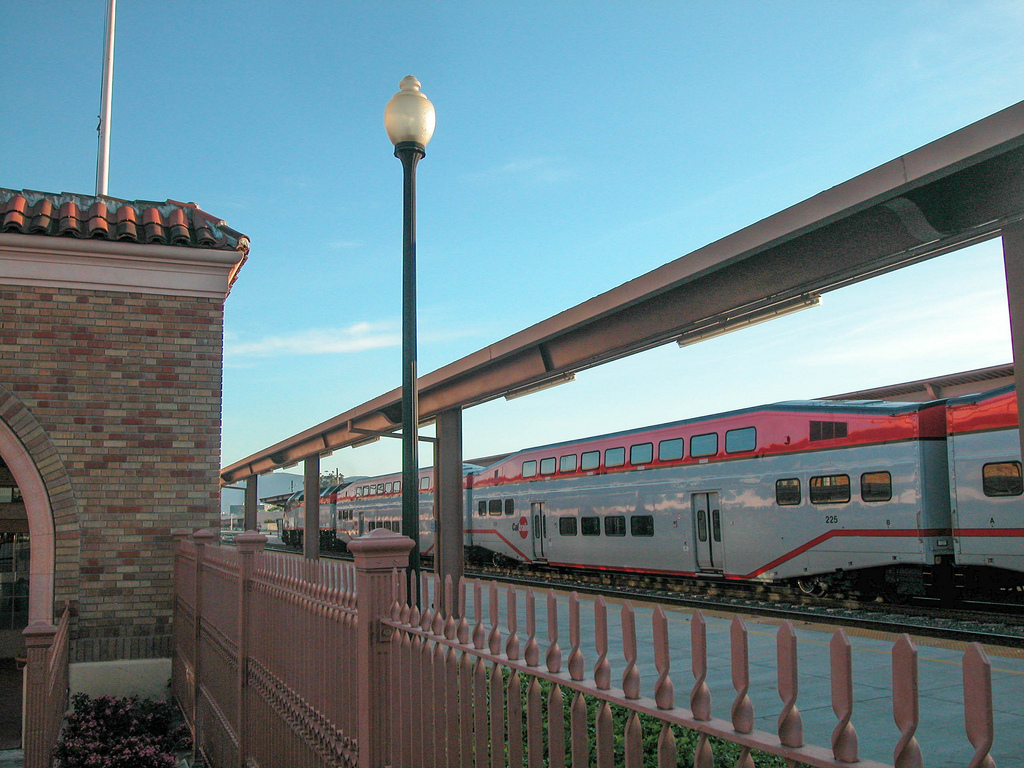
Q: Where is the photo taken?
A: Train station.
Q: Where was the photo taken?
A: At a train station.